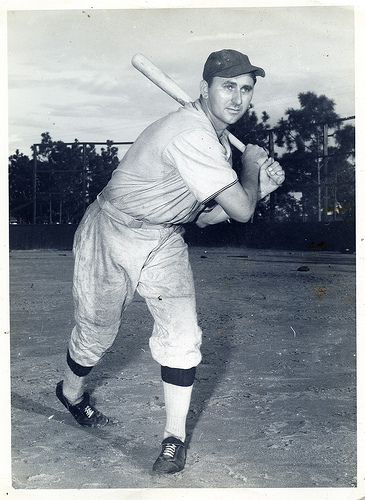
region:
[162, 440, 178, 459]
white shoe laces on a black shoe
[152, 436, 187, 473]
a black baseball shoe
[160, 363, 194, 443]
white and black knee high sock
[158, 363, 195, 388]
black band at the top of a sock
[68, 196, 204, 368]
dirty baseball uniform pants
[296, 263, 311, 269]
a large black rock on the ground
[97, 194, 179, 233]
a white uniform belt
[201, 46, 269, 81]
a dark baseball cap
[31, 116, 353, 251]
a tall metal fence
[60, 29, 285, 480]
this is a person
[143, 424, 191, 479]
this is a shoe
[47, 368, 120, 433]
this is a shoe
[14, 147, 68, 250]
this is a tree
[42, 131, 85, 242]
this is a tree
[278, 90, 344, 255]
this is a tree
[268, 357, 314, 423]
the ground is grey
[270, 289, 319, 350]
the ground is grey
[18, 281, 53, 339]
the ground is grey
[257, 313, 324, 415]
grey dirt of the baseball field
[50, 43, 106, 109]
grey cloudy skies over the field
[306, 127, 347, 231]
metal chain link fence surrounding the field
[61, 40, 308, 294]
a man holding a wood baseball bat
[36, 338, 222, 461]
the man's long black and white socks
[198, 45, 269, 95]
black baseball cap on the man's head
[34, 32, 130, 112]
white fluffy clouds in the sky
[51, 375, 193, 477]
the man's black cleats with white laces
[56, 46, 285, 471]
a man wearing a white baseball uniform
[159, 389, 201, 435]
the sock is long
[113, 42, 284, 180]
bat in the hands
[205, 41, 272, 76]
hat on the head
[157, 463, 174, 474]
the shoe is black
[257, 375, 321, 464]
the ground is cracked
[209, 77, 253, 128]
face of the man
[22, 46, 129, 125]
the sky is cloudy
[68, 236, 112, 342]
the pants are dirty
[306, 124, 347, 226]
trees over the fence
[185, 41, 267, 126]
head of a person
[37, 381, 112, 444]
feet of a person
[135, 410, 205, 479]
feet of a person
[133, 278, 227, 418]
leg of a person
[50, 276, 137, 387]
leg of a person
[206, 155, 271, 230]
arm of a person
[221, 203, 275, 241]
elbow of a person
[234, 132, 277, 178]
hand of a person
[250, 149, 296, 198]
hand of a person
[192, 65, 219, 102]
ear of a person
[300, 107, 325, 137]
leaves on the tree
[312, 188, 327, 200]
leaves on the tree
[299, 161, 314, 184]
leaves on the tree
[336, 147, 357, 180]
leaves on the tree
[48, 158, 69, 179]
leaves on the tree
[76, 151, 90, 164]
leaves on the tree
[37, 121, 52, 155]
leaves on the tree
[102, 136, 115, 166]
leaves on the tree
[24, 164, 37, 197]
leaves on the tree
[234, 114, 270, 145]
leaves on the tree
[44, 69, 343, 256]
a black and white photo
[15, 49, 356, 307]
a baseball player posing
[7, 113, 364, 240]
a tall fence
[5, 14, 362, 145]
a sky with clouds